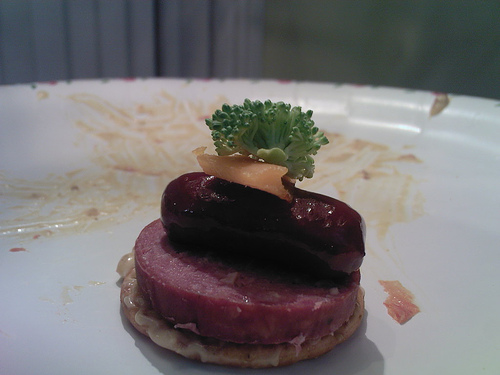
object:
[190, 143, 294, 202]
cheese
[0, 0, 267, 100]
blinds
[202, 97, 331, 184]
broccoli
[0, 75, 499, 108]
plate edge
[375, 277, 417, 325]
sauce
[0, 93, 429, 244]
sauce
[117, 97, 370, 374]
food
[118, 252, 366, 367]
cracker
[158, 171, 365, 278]
ham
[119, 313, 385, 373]
shadow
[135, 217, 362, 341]
meat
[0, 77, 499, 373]
dish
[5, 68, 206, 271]
stains